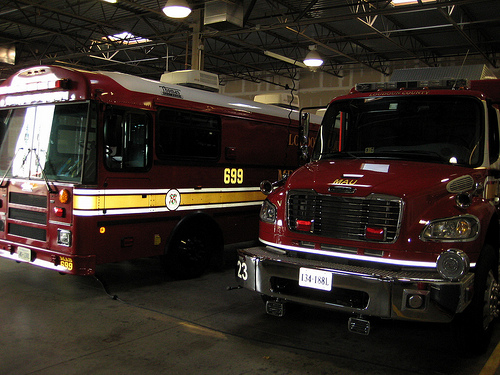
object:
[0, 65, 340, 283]
bus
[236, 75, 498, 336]
fire truck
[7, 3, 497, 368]
garage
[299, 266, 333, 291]
license plate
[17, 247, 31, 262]
license plate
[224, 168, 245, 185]
gold number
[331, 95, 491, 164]
windshield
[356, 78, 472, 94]
lights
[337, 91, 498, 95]
roof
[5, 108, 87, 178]
windshield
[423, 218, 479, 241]
headlight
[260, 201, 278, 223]
headlight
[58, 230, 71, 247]
headlight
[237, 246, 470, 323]
bumper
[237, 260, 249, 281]
number 23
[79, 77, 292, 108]
roof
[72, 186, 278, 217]
lines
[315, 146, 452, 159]
wipers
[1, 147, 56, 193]
wipers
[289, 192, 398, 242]
grill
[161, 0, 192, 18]
light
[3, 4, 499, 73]
ceiling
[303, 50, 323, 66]
light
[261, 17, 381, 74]
steel girders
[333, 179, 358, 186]
tag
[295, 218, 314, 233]
emergency light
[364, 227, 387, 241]
emergency lights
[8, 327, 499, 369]
floor